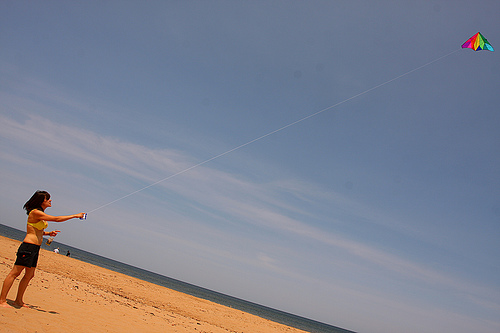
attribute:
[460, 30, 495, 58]
kite — colorful, multicolored, flying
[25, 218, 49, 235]
top — bikini, yellow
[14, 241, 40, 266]
shorts — dark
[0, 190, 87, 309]
kite flyer — lady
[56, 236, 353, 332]
beach — sandy, brown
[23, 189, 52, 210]
hair — brown, long, dark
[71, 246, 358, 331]
ocean — blue, calm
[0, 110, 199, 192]
clouds — white, whispy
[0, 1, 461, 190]
sky — wide open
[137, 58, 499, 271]
sky — bright